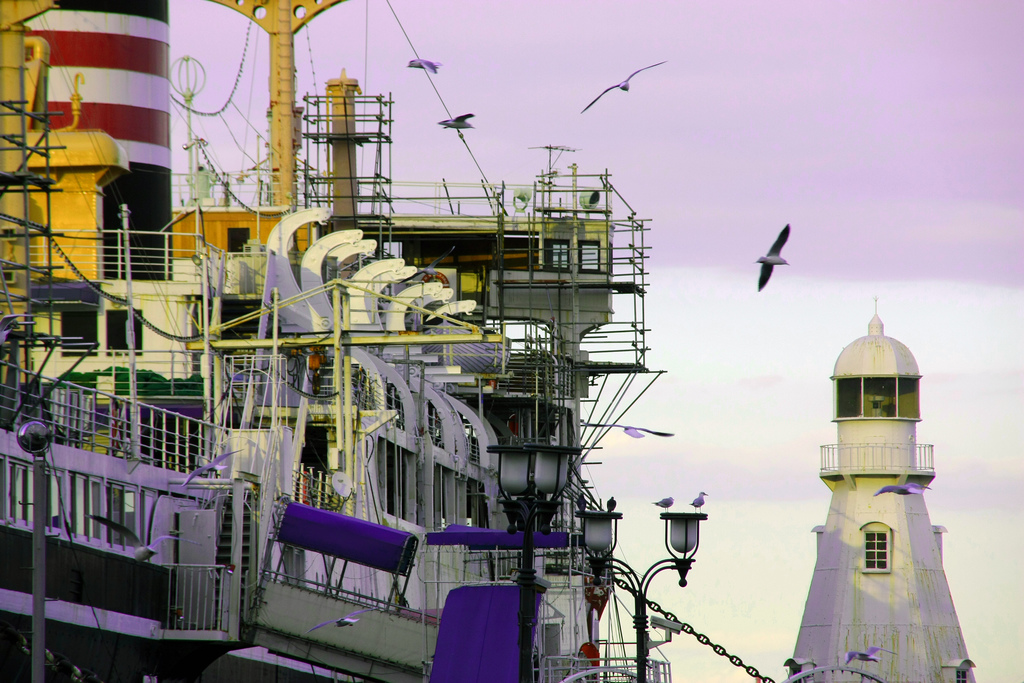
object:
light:
[661, 509, 717, 596]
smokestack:
[39, 0, 183, 285]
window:
[294, 421, 334, 511]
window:
[384, 373, 408, 434]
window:
[455, 409, 482, 465]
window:
[225, 226, 251, 259]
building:
[168, 158, 616, 470]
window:
[834, 374, 864, 418]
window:
[860, 374, 899, 416]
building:
[772, 288, 967, 683]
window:
[857, 520, 893, 574]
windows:
[577, 240, 600, 272]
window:
[105, 309, 143, 357]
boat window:
[577, 239, 600, 273]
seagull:
[653, 497, 675, 514]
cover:
[277, 501, 419, 573]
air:
[168, 1, 1024, 683]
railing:
[813, 443, 938, 477]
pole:
[573, 507, 704, 683]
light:
[576, 513, 624, 604]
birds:
[576, 491, 710, 513]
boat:
[2, 0, 709, 683]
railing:
[53, 380, 228, 483]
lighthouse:
[781, 288, 985, 681]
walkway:
[816, 441, 941, 490]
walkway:
[248, 479, 448, 676]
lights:
[572, 508, 706, 560]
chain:
[593, 569, 785, 683]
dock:
[690, 635, 980, 668]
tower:
[210, 0, 338, 214]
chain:
[166, 12, 255, 117]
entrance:
[248, 482, 531, 683]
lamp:
[573, 488, 717, 683]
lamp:
[484, 441, 580, 683]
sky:
[168, 0, 1024, 683]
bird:
[578, 61, 667, 115]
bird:
[437, 113, 479, 132]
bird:
[404, 58, 444, 74]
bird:
[754, 222, 793, 292]